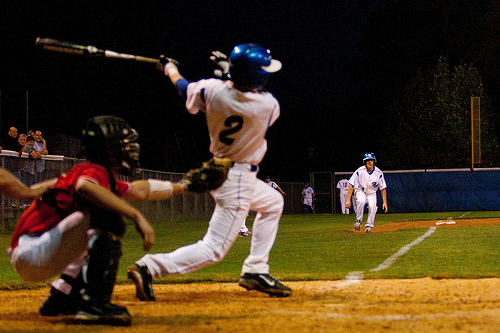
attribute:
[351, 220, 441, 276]
stripes — white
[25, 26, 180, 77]
bat — baseball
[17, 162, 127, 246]
jersey — red 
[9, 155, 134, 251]
jersey — red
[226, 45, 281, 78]
helmet — blue 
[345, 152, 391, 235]
man — bent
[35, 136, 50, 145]
spectator — watching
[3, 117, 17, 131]
spectator — watching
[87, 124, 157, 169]
mask — face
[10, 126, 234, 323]
child — ready to catch ball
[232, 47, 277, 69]
helmet — blue 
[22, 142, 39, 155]
green shirt — green 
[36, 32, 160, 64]
bat — baseball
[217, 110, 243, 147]
number — 2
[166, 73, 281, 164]
shirt — back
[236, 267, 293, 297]
nike cleat — Nike 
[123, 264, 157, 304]
nike cleat — Nike 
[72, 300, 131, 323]
nike cleat — Nike 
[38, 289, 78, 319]
nike cleat — Nike 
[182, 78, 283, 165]
jersey — white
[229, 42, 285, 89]
helmet — blue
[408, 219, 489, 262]
grass — green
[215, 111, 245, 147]
number — Big , blue 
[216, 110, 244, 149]
number — big, blue 